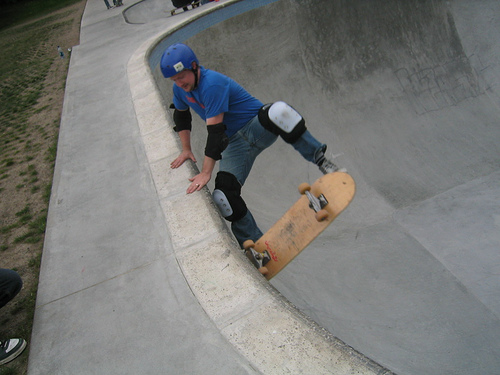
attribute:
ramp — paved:
[149, 27, 469, 373]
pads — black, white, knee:
[247, 98, 306, 147]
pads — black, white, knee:
[212, 168, 244, 227]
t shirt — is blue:
[169, 68, 263, 143]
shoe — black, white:
[0, 333, 27, 366]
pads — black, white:
[269, 100, 297, 130]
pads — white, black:
[210, 186, 236, 221]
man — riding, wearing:
[161, 43, 348, 248]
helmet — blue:
[152, 41, 202, 81]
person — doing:
[148, 36, 348, 268]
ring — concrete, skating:
[122, 2, 495, 371]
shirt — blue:
[168, 67, 266, 140]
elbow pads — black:
[202, 120, 230, 162]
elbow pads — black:
[169, 102, 193, 132]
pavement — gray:
[80, 277, 247, 349]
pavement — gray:
[25, 0, 497, 373]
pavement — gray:
[34, 34, 212, 374]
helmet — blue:
[157, 41, 212, 85]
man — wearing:
[113, 43, 413, 223]